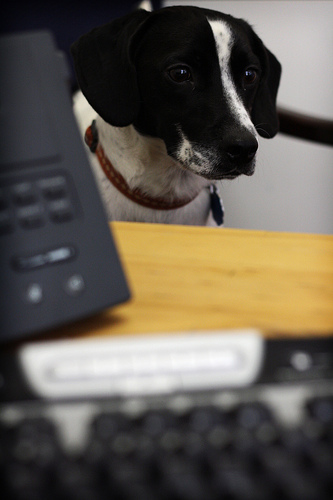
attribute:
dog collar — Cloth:
[84, 124, 203, 210]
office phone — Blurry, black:
[1, 32, 129, 340]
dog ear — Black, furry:
[76, 10, 161, 126]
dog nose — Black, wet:
[229, 127, 256, 160]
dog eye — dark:
[242, 69, 255, 80]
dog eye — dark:
[168, 63, 197, 82]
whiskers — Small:
[212, 176, 241, 189]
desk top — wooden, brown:
[38, 220, 331, 340]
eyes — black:
[163, 62, 258, 83]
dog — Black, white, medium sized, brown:
[70, 5, 281, 224]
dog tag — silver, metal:
[211, 184, 226, 226]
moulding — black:
[274, 109, 328, 149]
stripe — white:
[208, 12, 256, 139]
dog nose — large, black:
[225, 124, 260, 163]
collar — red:
[83, 124, 224, 225]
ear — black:
[50, 4, 156, 131]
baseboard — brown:
[276, 102, 328, 151]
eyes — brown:
[170, 59, 253, 86]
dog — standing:
[58, 0, 288, 225]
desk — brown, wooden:
[95, 215, 332, 338]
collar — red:
[84, 118, 202, 214]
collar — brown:
[79, 121, 201, 210]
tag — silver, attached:
[202, 177, 229, 229]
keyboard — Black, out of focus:
[4, 322, 330, 496]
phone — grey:
[3, 6, 136, 353]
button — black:
[43, 200, 70, 218]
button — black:
[12, 169, 34, 207]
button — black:
[14, 200, 51, 232]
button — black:
[22, 249, 44, 274]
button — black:
[65, 275, 82, 298]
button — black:
[19, 279, 51, 305]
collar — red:
[107, 158, 195, 218]